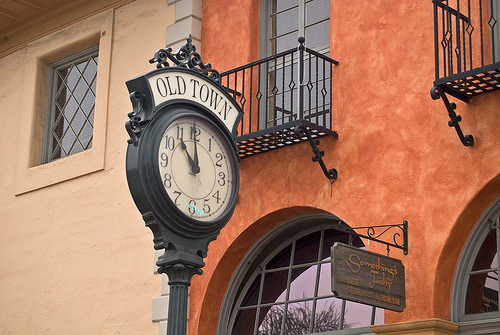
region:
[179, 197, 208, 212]
blue mark is spotted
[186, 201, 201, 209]
blue mark is spotted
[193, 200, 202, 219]
blue mark is spotted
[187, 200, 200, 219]
blue mark is spotted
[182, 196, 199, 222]
blue mark is spotted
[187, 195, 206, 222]
blue mark is spotted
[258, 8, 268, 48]
green paint on window frame.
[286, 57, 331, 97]
iron fence on balcony.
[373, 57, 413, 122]
orange paint on the wall.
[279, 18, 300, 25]
closed white window blinds.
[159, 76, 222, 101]
writing above the clock.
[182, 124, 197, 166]
black hands on the clock.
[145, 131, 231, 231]
clock on metal pole.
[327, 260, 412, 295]
sign hanging from building.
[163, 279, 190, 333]
pole supporting the clock.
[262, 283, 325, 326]
reflection in the window.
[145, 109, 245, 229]
clock with white face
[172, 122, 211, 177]
black hands on clock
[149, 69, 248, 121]
two words over clock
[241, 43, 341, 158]
black railing on balcony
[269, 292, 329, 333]
reflection on window pane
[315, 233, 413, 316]
sign hanging from metal brace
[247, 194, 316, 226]
arch in orange wall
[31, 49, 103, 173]
window with diagonal panes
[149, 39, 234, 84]
decoration on top of sign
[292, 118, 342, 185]
black brace under balcony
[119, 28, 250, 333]
black metal clock frame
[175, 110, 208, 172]
black hands of a clock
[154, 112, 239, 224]
white colored clock face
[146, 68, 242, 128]
words "old town" on a clock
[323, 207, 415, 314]
shop sign attached to a building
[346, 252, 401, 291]
name of the shop on the sign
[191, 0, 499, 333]
darker orange section of the building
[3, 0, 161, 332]
salmon colored section of the building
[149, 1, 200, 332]
row of vertical bricks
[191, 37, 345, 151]
black metal balconied area beneath a window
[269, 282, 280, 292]
the window is glass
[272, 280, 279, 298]
the window is glass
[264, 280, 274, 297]
the window is glass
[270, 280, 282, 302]
the window is glass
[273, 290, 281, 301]
the window is glass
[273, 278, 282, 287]
the window is glass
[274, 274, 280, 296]
the window is glass